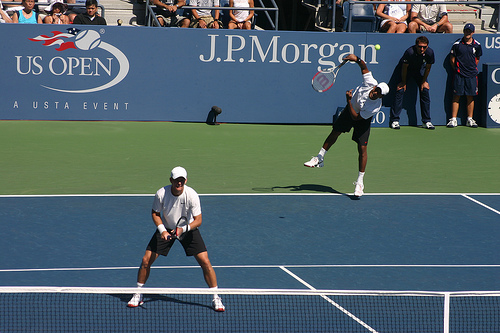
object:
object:
[204, 106, 223, 126]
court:
[2, 119, 499, 332]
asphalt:
[1, 121, 499, 194]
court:
[0, 194, 499, 333]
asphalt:
[3, 195, 500, 332]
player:
[126, 165, 225, 312]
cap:
[169, 166, 188, 180]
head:
[170, 166, 188, 193]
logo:
[16, 28, 129, 95]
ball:
[74, 29, 100, 51]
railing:
[142, 1, 280, 28]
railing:
[292, 1, 496, 32]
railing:
[0, 3, 105, 26]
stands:
[1, 1, 497, 34]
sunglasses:
[417, 45, 428, 49]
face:
[416, 41, 428, 51]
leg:
[302, 106, 353, 170]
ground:
[2, 121, 499, 333]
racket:
[310, 59, 348, 94]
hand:
[343, 53, 358, 65]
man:
[304, 54, 390, 199]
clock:
[487, 92, 500, 127]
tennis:
[1, 25, 500, 332]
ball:
[374, 43, 380, 52]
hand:
[396, 82, 408, 93]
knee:
[394, 80, 408, 94]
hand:
[420, 79, 431, 93]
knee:
[419, 79, 429, 96]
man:
[390, 36, 436, 130]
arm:
[449, 40, 459, 69]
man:
[446, 25, 486, 129]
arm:
[476, 38, 483, 67]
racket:
[169, 216, 190, 245]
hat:
[372, 82, 389, 97]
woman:
[11, 1, 43, 24]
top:
[18, 10, 38, 24]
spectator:
[45, 3, 69, 28]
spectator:
[74, 1, 106, 26]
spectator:
[154, 2, 194, 30]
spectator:
[190, 2, 222, 31]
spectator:
[229, 1, 258, 31]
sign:
[200, 33, 380, 67]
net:
[1, 286, 499, 332]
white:
[277, 263, 376, 332]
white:
[2, 263, 500, 275]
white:
[463, 194, 500, 215]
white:
[1, 189, 500, 200]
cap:
[463, 23, 474, 35]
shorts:
[332, 106, 371, 146]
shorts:
[147, 226, 207, 257]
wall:
[0, 25, 499, 126]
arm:
[151, 190, 171, 242]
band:
[157, 225, 166, 235]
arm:
[169, 189, 203, 239]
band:
[180, 225, 191, 233]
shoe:
[302, 153, 325, 170]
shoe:
[353, 182, 366, 198]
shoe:
[127, 296, 144, 308]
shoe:
[209, 294, 226, 313]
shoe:
[392, 121, 402, 132]